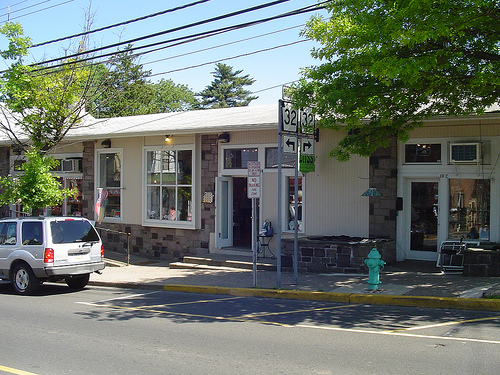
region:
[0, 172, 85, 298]
a car is at th roadside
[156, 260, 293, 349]
shadow of trees are on the floor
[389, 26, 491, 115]
the tree is next to the building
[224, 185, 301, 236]
the door is open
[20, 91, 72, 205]
the tee is next to the building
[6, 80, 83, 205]
the tree is green incolor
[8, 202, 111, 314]
the car i s gray in oclor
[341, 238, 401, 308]
the hydrant is beside the roiad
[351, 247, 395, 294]
the hydrant is green incolor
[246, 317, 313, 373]
the road ismade of asphalt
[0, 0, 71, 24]
Electrical wire in sky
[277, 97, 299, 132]
Black and white sign with 32 on it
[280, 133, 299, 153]
Sign with left arrow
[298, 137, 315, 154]
Sign with right arrow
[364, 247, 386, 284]
Green fire hydrant on sidewalk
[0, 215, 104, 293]
White SUV on road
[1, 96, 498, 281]
Long house on sidewalk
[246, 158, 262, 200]
Red and white street sign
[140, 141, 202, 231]
White paned window on building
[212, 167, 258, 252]
White open door on building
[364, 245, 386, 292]
Green fire hydrant on sidewalk.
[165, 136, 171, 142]
Bare light bulb outside of building.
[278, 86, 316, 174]
Traffic directional signs on sidewalk.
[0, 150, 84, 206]
Green bright leaves on tree.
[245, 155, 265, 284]
No parking sign on sidewalk.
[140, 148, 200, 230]
White framed six pane window.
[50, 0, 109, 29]
Bright blue sky during morning.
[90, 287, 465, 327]
Yellow parking lines on street.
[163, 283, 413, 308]
Yellow painted curb near sidewalk.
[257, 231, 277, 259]
Small table outside building.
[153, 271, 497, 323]
edge of sidewalk is yellow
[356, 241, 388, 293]
fire hydrant is turquoise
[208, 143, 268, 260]
door of building is open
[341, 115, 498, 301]
fire hydrant in front a door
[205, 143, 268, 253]
window above a door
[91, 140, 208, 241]
white windows on building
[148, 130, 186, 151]
a light on ceiling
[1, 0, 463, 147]
power lines above the road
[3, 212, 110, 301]
a gray car on side road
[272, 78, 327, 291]
street signs on sidewalk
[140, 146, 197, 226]
window on a one story building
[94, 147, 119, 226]
window on a one story building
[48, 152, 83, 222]
window on a one story building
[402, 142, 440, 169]
window on a one story building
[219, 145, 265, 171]
window on a one story building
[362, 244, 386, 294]
green hydrant by a building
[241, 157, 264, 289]
street sign on a metal pole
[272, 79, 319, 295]
street sign on a metal pole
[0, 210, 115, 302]
car parked on the street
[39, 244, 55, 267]
tail light of a car